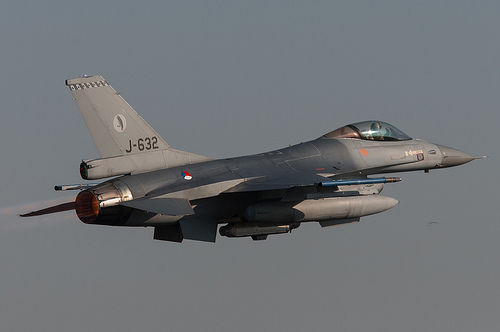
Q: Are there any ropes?
A: No, there are no ropes.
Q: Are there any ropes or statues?
A: No, there are no ropes or statues.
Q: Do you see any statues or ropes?
A: No, there are no ropes or statues.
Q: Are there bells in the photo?
A: No, there are no bells.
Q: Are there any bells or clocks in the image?
A: No, there are no bells or clocks.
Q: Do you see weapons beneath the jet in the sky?
A: Yes, there is a weapon beneath the jet.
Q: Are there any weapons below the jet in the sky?
A: Yes, there is a weapon below the jet.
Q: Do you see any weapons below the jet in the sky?
A: Yes, there is a weapon below the jet.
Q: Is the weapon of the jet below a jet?
A: Yes, the weapon is below a jet.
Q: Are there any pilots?
A: Yes, there is a pilot.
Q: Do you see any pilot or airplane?
A: Yes, there is a pilot.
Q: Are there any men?
A: No, there are no men.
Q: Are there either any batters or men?
A: No, there are no men or batters.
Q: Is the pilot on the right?
A: Yes, the pilot is on the right of the image.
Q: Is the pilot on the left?
A: No, the pilot is on the right of the image.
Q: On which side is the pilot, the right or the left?
A: The pilot is on the right of the image.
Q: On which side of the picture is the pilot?
A: The pilot is on the right of the image.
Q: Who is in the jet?
A: The pilot is in the jet.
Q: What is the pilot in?
A: The pilot is in the jet.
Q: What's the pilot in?
A: The pilot is in the jet.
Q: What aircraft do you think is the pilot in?
A: The pilot is in the jet.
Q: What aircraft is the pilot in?
A: The pilot is in the jet.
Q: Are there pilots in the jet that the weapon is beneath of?
A: Yes, there is a pilot in the jet.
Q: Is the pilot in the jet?
A: Yes, the pilot is in the jet.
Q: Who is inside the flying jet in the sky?
A: The pilot is inside the jet.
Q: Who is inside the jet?
A: The pilot is inside the jet.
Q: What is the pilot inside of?
A: The pilot is inside the jet.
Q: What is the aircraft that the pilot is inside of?
A: The aircraft is a jet.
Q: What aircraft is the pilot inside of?
A: The pilot is inside the jet.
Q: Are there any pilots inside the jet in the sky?
A: Yes, there is a pilot inside the jet.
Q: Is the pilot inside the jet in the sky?
A: Yes, the pilot is inside the jet.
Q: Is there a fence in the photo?
A: No, there are no fences.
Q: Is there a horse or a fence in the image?
A: No, there are no fences or horses.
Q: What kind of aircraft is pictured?
A: The aircraft is a jet.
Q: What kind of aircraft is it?
A: The aircraft is a jet.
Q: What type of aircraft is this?
A: That is a jet.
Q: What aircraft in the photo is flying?
A: The aircraft is a jet.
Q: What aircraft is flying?
A: The aircraft is a jet.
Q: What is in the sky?
A: The jet is in the sky.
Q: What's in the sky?
A: The jet is in the sky.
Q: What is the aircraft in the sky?
A: The aircraft is a jet.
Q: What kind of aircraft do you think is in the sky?
A: The aircraft is a jet.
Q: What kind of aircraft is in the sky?
A: The aircraft is a jet.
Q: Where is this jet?
A: The jet is in the sky.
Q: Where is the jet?
A: The jet is in the sky.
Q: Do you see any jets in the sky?
A: Yes, there is a jet in the sky.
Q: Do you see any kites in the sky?
A: No, there is a jet in the sky.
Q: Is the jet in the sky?
A: Yes, the jet is in the sky.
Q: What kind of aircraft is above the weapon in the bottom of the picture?
A: The aircraft is a jet.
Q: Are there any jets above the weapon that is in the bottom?
A: Yes, there is a jet above the weapon.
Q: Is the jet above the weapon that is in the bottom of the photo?
A: Yes, the jet is above the weapon.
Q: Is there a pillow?
A: No, there are no pillows.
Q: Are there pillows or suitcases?
A: No, there are no pillows or suitcases.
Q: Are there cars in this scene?
A: No, there are no cars.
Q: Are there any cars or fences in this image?
A: No, there are no cars or fences.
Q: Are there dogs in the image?
A: No, there are no dogs.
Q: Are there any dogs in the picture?
A: No, there are no dogs.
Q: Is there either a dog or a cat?
A: No, there are no dogs or cats.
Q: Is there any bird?
A: No, there are no birds.